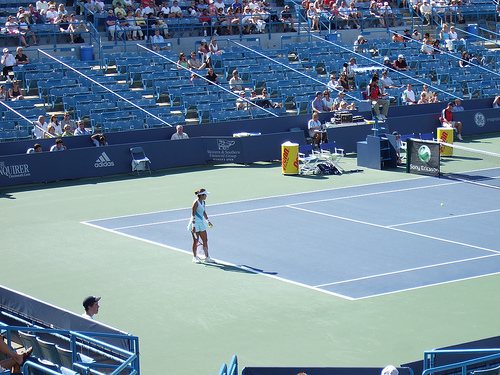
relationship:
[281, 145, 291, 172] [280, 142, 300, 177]
letters on can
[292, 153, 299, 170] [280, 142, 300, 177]
letters on can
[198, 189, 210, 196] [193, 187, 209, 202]
sun visor on head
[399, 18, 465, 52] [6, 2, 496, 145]
spectators sitting in stands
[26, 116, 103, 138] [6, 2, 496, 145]
spectators sitting in stands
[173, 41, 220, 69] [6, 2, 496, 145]
spectators sitting in stands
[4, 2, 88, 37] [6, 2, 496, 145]
spectators sitting in stands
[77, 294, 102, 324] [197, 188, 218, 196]
boy wearing cap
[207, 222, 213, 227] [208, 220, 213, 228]
tennis ball in hand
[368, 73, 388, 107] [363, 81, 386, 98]
man wearing red jacket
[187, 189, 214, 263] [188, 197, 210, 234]
box wearing dress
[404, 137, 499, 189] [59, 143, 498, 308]
net on court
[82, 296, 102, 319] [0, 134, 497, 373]
boy on court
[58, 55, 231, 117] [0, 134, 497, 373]
seats overlooking court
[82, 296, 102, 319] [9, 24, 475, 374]
boy on court